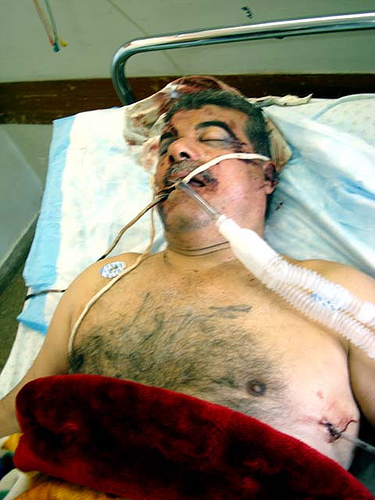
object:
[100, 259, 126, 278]
pads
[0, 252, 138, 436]
arm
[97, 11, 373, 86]
bar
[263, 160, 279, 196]
ear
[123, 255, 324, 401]
chest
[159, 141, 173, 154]
eye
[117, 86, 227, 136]
rag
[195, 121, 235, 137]
eyebrow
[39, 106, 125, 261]
cloth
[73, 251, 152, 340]
shoulder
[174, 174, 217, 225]
machine tube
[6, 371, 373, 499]
fabric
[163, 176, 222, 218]
tube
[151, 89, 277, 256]
head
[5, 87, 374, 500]
injured man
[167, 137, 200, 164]
nose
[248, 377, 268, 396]
nipple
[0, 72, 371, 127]
board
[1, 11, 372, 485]
hospital bed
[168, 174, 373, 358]
breathing tube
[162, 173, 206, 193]
mouth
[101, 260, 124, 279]
electrical patch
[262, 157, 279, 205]
blood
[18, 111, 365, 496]
hospital bed